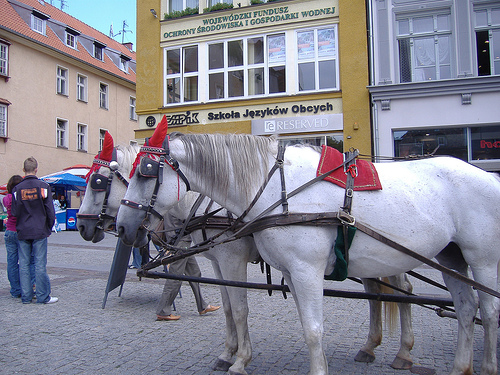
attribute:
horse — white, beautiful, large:
[110, 111, 496, 366]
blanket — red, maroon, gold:
[313, 142, 383, 192]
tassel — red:
[126, 115, 170, 186]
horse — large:
[70, 129, 422, 366]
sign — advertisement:
[94, 202, 140, 316]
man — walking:
[144, 232, 224, 323]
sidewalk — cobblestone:
[5, 221, 498, 365]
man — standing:
[15, 155, 57, 309]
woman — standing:
[1, 174, 21, 299]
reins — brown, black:
[291, 144, 377, 200]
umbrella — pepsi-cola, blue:
[38, 164, 91, 192]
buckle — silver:
[331, 210, 357, 229]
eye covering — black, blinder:
[137, 159, 161, 181]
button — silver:
[146, 161, 152, 168]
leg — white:
[277, 246, 331, 373]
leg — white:
[227, 247, 251, 373]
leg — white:
[351, 269, 388, 365]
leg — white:
[470, 260, 496, 370]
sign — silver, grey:
[251, 115, 341, 142]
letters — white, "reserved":
[267, 116, 329, 134]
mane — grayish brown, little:
[170, 124, 283, 207]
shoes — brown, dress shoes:
[155, 303, 222, 325]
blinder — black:
[84, 176, 117, 192]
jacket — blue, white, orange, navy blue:
[8, 178, 64, 240]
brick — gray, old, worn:
[371, 5, 497, 181]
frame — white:
[162, 25, 342, 110]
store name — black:
[208, 101, 340, 125]